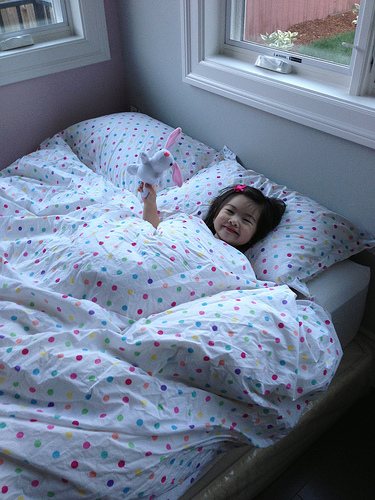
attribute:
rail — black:
[2, 3, 57, 29]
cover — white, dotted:
[4, 241, 190, 412]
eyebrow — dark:
[228, 201, 237, 210]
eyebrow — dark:
[242, 208, 257, 221]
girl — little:
[137, 176, 282, 254]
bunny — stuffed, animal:
[127, 126, 182, 197]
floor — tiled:
[298, 428, 374, 491]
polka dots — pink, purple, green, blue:
[1, 111, 373, 497]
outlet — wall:
[128, 102, 144, 113]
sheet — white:
[316, 247, 373, 324]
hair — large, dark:
[223, 180, 299, 229]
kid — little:
[175, 177, 292, 276]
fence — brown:
[244, 2, 354, 41]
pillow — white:
[57, 108, 219, 198]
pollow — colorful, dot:
[152, 142, 373, 285]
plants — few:
[259, 3, 360, 50]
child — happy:
[135, 180, 286, 254]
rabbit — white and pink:
[121, 128, 186, 203]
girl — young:
[123, 159, 303, 305]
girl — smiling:
[100, 170, 269, 305]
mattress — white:
[1, 108, 365, 398]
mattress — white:
[255, 366, 357, 465]